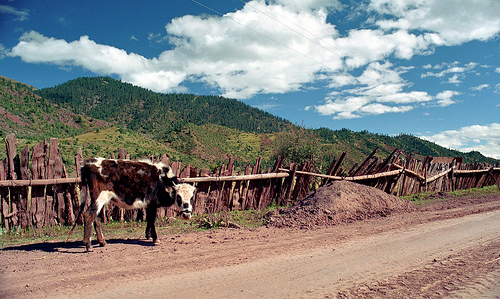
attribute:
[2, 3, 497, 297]
scene — beautiful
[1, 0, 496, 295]
countryside — picturesque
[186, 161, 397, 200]
fence — Sticks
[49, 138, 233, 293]
cow — brown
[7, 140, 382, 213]
fence/sticks — farm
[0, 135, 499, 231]
fence — wood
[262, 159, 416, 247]
mound — small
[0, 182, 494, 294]
road — dusty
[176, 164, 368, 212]
board — old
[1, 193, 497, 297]
road — dusty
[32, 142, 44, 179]
hair — cow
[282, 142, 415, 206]
leaning fence — uneven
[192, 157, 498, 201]
fence — unusual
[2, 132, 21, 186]
board — brown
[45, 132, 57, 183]
board — rugged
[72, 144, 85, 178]
board — old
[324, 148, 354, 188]
board — splintered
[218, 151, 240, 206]
board — seasoned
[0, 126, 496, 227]
fence — nearby, leaning, seasoned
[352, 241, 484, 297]
tracks — deep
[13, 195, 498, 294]
dirt road — narrow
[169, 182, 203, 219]
cow — looking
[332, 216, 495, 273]
dirt — brown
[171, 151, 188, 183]
board — nearby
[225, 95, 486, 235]
fence — unique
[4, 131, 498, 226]
elephant — nonexistant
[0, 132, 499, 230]
sticks — many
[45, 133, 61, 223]
board — nearby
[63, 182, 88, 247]
tail — long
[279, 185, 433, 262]
dirt — brown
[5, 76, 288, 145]
mountain — distant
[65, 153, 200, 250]
cow — farm, white, brown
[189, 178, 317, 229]
fence — farm